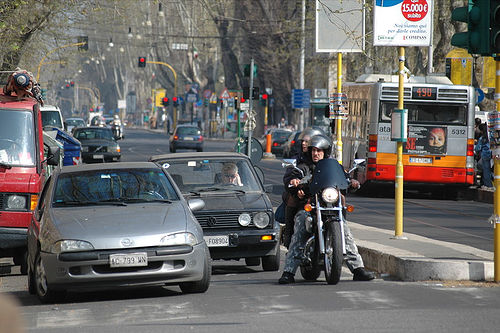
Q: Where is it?
A: This is at the roadway.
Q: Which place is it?
A: It is a roadway.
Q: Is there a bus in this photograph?
A: Yes, there is a bus.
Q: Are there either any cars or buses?
A: Yes, there is a bus.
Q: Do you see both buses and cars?
A: Yes, there are both a bus and a car.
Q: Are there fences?
A: No, there are no fences.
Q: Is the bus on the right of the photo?
A: Yes, the bus is on the right of the image.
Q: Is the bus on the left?
A: No, the bus is on the right of the image.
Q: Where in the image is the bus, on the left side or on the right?
A: The bus is on the right of the image.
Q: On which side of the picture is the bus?
A: The bus is on the right of the image.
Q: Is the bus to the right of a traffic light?
A: Yes, the bus is to the right of a traffic light.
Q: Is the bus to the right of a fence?
A: No, the bus is to the right of a traffic light.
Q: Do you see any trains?
A: No, there are no trains.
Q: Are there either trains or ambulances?
A: No, there are no trains or ambulances.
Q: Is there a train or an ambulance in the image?
A: No, there are no trains or ambulances.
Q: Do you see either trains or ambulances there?
A: No, there are no trains or ambulances.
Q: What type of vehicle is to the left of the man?
A: The vehicle is a car.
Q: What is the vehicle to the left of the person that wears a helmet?
A: The vehicle is a car.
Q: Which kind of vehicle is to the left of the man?
A: The vehicle is a car.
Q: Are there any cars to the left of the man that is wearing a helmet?
A: Yes, there is a car to the left of the man.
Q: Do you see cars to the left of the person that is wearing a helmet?
A: Yes, there is a car to the left of the man.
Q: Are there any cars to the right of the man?
A: No, the car is to the left of the man.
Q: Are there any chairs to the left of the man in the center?
A: No, there is a car to the left of the man.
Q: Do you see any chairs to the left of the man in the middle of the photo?
A: No, there is a car to the left of the man.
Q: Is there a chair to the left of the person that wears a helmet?
A: No, there is a car to the left of the man.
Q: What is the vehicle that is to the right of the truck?
A: The vehicle is a car.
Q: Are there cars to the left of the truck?
A: No, the car is to the right of the truck.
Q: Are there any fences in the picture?
A: No, there are no fences.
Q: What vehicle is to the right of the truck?
A: The vehicle is a car.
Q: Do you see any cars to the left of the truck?
A: No, the car is to the right of the truck.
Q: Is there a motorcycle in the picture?
A: Yes, there is a motorcycle.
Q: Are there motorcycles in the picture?
A: Yes, there is a motorcycle.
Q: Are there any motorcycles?
A: Yes, there is a motorcycle.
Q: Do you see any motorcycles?
A: Yes, there is a motorcycle.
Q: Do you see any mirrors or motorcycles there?
A: Yes, there is a motorcycle.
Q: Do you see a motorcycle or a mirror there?
A: Yes, there is a motorcycle.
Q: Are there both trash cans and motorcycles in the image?
A: No, there is a motorcycle but no trash cans.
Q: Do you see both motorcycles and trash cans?
A: No, there is a motorcycle but no trash cans.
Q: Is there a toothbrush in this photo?
A: No, there are no toothbrushes.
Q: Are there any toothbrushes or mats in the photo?
A: No, there are no toothbrushes or mats.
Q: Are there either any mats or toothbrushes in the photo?
A: No, there are no toothbrushes or mats.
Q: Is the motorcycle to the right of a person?
A: Yes, the motorcycle is to the right of a person.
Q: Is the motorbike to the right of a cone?
A: No, the motorbike is to the right of a person.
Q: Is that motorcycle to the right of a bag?
A: No, the motorcycle is to the right of a car.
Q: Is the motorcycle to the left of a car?
A: No, the motorcycle is to the right of a car.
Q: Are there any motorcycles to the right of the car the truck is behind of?
A: Yes, there is a motorcycle to the right of the car.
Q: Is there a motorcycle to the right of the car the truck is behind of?
A: Yes, there is a motorcycle to the right of the car.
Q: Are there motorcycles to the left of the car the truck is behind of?
A: No, the motorcycle is to the right of the car.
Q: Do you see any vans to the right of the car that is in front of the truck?
A: No, there is a motorcycle to the right of the car.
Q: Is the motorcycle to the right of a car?
A: Yes, the motorcycle is to the right of a car.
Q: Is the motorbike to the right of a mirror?
A: No, the motorbike is to the right of a car.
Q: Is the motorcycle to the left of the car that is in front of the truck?
A: No, the motorcycle is to the right of the car.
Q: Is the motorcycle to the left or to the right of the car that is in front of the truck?
A: The motorcycle is to the right of the car.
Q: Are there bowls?
A: No, there are no bowls.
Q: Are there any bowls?
A: No, there are no bowls.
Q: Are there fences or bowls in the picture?
A: No, there are no bowls or fences.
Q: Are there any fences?
A: No, there are no fences.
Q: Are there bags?
A: No, there are no bags.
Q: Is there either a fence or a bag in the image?
A: No, there are no bags or fences.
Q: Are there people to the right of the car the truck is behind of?
A: Yes, there is a person to the right of the car.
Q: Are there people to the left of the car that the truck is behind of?
A: No, the person is to the right of the car.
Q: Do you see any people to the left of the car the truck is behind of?
A: No, the person is to the right of the car.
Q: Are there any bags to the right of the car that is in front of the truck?
A: No, there is a person to the right of the car.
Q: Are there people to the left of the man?
A: Yes, there is a person to the left of the man.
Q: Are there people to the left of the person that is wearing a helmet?
A: Yes, there is a person to the left of the man.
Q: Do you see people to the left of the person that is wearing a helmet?
A: Yes, there is a person to the left of the man.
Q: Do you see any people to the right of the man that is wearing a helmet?
A: No, the person is to the left of the man.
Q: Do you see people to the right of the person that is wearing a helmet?
A: No, the person is to the left of the man.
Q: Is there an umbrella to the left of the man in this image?
A: No, there is a person to the left of the man.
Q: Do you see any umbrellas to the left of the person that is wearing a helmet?
A: No, there is a person to the left of the man.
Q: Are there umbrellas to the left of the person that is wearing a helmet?
A: No, there is a person to the left of the man.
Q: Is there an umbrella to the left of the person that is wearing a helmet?
A: No, there is a person to the left of the man.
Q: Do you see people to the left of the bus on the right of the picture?
A: Yes, there is a person to the left of the bus.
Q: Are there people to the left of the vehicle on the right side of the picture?
A: Yes, there is a person to the left of the bus.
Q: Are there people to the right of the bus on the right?
A: No, the person is to the left of the bus.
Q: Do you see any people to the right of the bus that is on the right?
A: No, the person is to the left of the bus.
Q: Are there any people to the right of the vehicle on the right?
A: No, the person is to the left of the bus.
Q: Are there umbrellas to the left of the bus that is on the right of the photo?
A: No, there is a person to the left of the bus.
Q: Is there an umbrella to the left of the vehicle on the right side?
A: No, there is a person to the left of the bus.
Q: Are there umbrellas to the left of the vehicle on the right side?
A: No, there is a person to the left of the bus.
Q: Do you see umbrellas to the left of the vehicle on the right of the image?
A: No, there is a person to the left of the bus.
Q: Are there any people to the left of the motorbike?
A: Yes, there is a person to the left of the motorbike.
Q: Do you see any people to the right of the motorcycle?
A: No, the person is to the left of the motorcycle.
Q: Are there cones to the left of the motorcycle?
A: No, there is a person to the left of the motorcycle.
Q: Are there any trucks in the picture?
A: Yes, there is a truck.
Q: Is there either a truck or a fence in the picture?
A: Yes, there is a truck.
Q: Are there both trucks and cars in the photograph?
A: Yes, there are both a truck and a car.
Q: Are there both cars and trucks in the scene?
A: Yes, there are both a truck and a car.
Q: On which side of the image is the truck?
A: The truck is on the left of the image.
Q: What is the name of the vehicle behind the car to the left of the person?
A: The vehicle is a truck.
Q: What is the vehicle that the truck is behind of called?
A: The vehicle is a car.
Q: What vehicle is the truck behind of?
A: The truck is behind the car.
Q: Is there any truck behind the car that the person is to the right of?
A: Yes, there is a truck behind the car.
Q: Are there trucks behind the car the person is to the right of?
A: Yes, there is a truck behind the car.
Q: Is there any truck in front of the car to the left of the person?
A: No, the truck is behind the car.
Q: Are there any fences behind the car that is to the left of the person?
A: No, there is a truck behind the car.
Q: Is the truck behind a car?
A: Yes, the truck is behind a car.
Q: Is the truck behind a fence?
A: No, the truck is behind a car.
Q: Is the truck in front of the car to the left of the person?
A: No, the truck is behind the car.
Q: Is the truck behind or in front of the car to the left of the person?
A: The truck is behind the car.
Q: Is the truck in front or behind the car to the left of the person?
A: The truck is behind the car.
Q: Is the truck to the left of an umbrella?
A: No, the truck is to the left of a traffic light.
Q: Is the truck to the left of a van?
A: No, the truck is to the left of a traffic light.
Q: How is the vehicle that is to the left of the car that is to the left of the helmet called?
A: The vehicle is a truck.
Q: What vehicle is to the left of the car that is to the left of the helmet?
A: The vehicle is a truck.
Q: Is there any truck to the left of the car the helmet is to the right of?
A: Yes, there is a truck to the left of the car.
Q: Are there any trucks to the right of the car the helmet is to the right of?
A: No, the truck is to the left of the car.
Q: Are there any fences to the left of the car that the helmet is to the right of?
A: No, there is a truck to the left of the car.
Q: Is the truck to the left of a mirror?
A: No, the truck is to the left of the car.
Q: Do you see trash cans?
A: No, there are no trash cans.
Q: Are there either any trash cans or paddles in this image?
A: No, there are no trash cans or paddles.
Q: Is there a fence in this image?
A: No, there are no fences.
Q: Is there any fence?
A: No, there are no fences.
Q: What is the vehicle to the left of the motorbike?
A: The vehicle is a car.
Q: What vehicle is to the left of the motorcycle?
A: The vehicle is a car.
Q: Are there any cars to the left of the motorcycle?
A: Yes, there is a car to the left of the motorcycle.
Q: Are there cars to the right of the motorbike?
A: No, the car is to the left of the motorbike.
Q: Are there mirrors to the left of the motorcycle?
A: No, there is a car to the left of the motorcycle.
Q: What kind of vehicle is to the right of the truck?
A: The vehicle is a car.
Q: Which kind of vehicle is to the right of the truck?
A: The vehicle is a car.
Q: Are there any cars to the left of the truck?
A: No, the car is to the right of the truck.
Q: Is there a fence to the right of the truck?
A: No, there is a car to the right of the truck.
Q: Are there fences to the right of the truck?
A: No, there is a car to the right of the truck.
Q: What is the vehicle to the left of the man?
A: The vehicle is a car.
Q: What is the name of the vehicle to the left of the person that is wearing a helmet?
A: The vehicle is a car.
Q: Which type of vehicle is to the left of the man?
A: The vehicle is a car.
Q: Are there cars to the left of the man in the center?
A: Yes, there is a car to the left of the man.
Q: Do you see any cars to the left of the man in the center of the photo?
A: Yes, there is a car to the left of the man.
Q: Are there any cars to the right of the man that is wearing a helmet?
A: No, the car is to the left of the man.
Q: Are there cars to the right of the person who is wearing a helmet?
A: No, the car is to the left of the man.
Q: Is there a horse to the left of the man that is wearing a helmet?
A: No, there is a car to the left of the man.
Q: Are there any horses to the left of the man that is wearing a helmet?
A: No, there is a car to the left of the man.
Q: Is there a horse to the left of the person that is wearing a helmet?
A: No, there is a car to the left of the man.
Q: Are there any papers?
A: No, there are no papers.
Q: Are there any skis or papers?
A: No, there are no papers or skis.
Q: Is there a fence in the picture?
A: No, there are no fences.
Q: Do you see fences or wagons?
A: No, there are no fences or wagons.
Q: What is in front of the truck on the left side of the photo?
A: The car is in front of the truck.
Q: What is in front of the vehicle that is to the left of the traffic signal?
A: The car is in front of the truck.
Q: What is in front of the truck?
A: The car is in front of the truck.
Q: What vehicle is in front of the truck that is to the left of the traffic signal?
A: The vehicle is a car.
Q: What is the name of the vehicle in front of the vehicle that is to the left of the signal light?
A: The vehicle is a car.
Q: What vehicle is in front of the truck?
A: The vehicle is a car.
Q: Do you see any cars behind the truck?
A: No, the car is in front of the truck.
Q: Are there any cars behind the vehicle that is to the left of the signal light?
A: No, the car is in front of the truck.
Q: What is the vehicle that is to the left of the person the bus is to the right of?
A: The vehicle is a car.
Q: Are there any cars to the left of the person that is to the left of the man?
A: Yes, there is a car to the left of the person.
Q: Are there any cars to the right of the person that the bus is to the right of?
A: No, the car is to the left of the person.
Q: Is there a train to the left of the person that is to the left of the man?
A: No, there is a car to the left of the person.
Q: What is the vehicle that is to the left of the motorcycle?
A: The vehicle is a car.